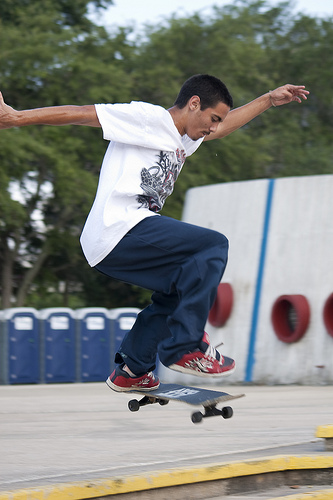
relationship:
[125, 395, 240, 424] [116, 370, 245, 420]
wheels are attached to skateboard